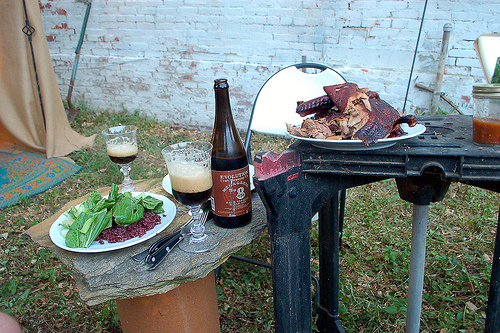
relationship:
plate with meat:
[285, 121, 431, 152] [288, 80, 428, 136]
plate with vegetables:
[49, 186, 177, 258] [60, 178, 166, 247]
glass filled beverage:
[158, 134, 233, 263] [171, 173, 217, 205]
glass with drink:
[158, 134, 233, 263] [171, 173, 217, 205]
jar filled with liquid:
[465, 77, 499, 151] [475, 113, 500, 141]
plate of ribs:
[285, 121, 431, 152] [288, 80, 428, 136]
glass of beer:
[158, 134, 233, 263] [171, 173, 217, 205]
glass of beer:
[99, 121, 151, 193] [104, 148, 139, 165]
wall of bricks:
[40, 2, 498, 137] [148, 9, 198, 30]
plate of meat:
[285, 121, 431, 152] [288, 80, 428, 136]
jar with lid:
[465, 77, 499, 151] [470, 82, 500, 104]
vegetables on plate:
[60, 178, 166, 247] [49, 186, 177, 258]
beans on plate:
[97, 209, 162, 243] [285, 121, 431, 152]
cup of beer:
[99, 121, 151, 193] [104, 148, 139, 165]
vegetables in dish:
[60, 178, 166, 247] [49, 186, 177, 258]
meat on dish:
[288, 80, 428, 136] [285, 121, 431, 152]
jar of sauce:
[465, 77, 499, 151] [475, 113, 500, 141]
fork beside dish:
[144, 212, 208, 268] [49, 186, 177, 258]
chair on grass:
[237, 58, 350, 211] [342, 187, 418, 332]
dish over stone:
[49, 186, 177, 258] [25, 168, 275, 309]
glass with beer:
[99, 121, 151, 193] [104, 148, 139, 165]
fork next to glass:
[144, 212, 208, 268] [158, 134, 233, 263]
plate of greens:
[49, 186, 177, 258] [60, 178, 166, 247]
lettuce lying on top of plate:
[49, 186, 177, 258] [47, 190, 177, 253]